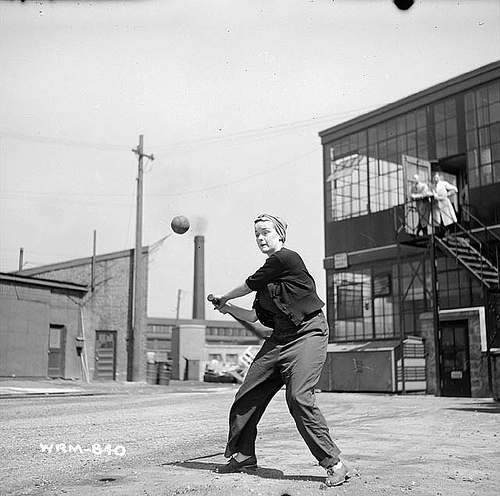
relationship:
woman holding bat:
[207, 212, 352, 486] [207, 290, 273, 339]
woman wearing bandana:
[207, 212, 352, 486] [252, 210, 287, 243]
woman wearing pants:
[207, 212, 352, 486] [224, 310, 340, 468]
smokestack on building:
[192, 234, 207, 320] [147, 315, 271, 380]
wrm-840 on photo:
[40, 442, 128, 458] [1, 1, 499, 494]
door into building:
[400, 152, 436, 238] [318, 58, 499, 399]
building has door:
[16, 247, 154, 386] [93, 328, 117, 383]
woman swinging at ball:
[207, 212, 352, 486] [171, 214, 191, 234]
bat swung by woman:
[207, 290, 273, 339] [207, 212, 352, 486]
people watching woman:
[409, 171, 459, 238] [207, 212, 352, 486]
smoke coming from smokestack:
[190, 215, 208, 237] [192, 234, 207, 320]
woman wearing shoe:
[207, 212, 352, 486] [213, 455, 260, 476]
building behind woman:
[318, 58, 499, 399] [207, 212, 352, 486]